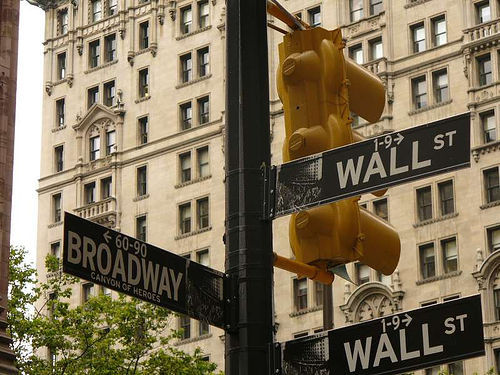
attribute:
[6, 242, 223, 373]
tree — green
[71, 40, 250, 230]
white building — large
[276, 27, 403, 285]
street signal — yellow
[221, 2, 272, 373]
pole — pictured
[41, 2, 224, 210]
building — pictured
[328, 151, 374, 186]
letter — white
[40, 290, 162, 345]
leaves — green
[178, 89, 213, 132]
windows — pictured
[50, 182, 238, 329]
sign — black, street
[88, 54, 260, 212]
wall — cream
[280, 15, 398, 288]
signal — traffic, yellow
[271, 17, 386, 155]
traffic light — pictured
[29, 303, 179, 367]
leaves — pictured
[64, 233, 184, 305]
lettering — white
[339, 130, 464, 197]
lettering — white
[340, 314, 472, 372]
lettering — white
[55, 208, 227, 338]
sign — black, street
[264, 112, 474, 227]
sign — black, street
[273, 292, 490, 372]
sign — black, street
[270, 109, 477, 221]
sign — black, street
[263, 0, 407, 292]
street signal — yellow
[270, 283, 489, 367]
street sign — black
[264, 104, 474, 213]
street sign — black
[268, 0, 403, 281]
traffic light — yellow